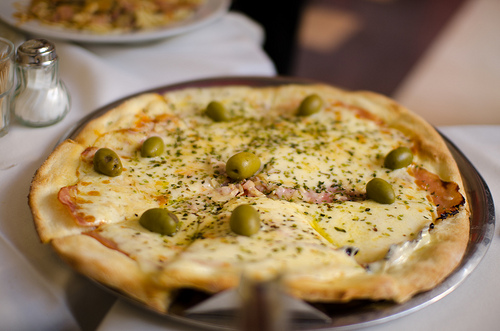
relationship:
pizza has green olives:
[101, 114, 432, 275] [209, 135, 282, 189]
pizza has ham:
[101, 114, 432, 275] [40, 185, 105, 229]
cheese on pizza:
[270, 129, 339, 195] [101, 114, 432, 275]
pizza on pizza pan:
[101, 114, 432, 275] [16, 72, 485, 319]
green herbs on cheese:
[260, 127, 346, 173] [270, 129, 339, 195]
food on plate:
[29, 4, 213, 49] [17, 27, 226, 44]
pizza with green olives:
[101, 114, 432, 275] [209, 135, 282, 189]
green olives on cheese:
[209, 135, 282, 189] [270, 129, 339, 195]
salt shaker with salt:
[2, 24, 71, 118] [15, 92, 69, 127]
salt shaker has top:
[2, 24, 71, 118] [10, 37, 58, 72]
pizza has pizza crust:
[101, 114, 432, 275] [339, 81, 448, 150]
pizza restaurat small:
[101, 114, 432, 275] [400, 66, 492, 131]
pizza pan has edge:
[16, 72, 485, 319] [191, 58, 256, 89]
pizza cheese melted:
[101, 114, 432, 275] [320, 212, 401, 262]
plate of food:
[17, 27, 226, 44] [29, 4, 213, 49]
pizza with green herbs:
[101, 114, 432, 275] [260, 127, 346, 173]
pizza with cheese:
[101, 114, 432, 275] [270, 129, 339, 195]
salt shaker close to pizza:
[2, 24, 71, 118] [101, 114, 432, 275]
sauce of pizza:
[346, 100, 387, 127] [101, 114, 432, 275]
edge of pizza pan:
[191, 58, 256, 89] [16, 72, 485, 319]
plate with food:
[17, 27, 226, 44] [29, 4, 213, 49]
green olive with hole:
[90, 139, 132, 187] [105, 150, 140, 181]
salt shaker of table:
[2, 24, 71, 118] [203, 29, 303, 77]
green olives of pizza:
[209, 135, 282, 189] [101, 114, 432, 275]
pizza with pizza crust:
[101, 114, 432, 275] [339, 81, 448, 150]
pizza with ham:
[101, 114, 432, 275] [40, 185, 105, 229]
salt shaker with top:
[2, 24, 71, 118] [10, 37, 58, 72]